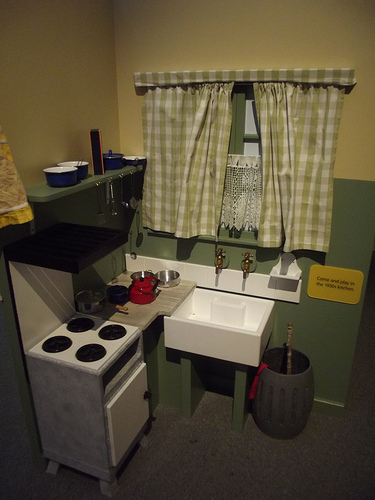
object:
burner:
[40, 335, 72, 355]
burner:
[63, 314, 95, 332]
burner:
[98, 321, 127, 339]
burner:
[74, 342, 106, 366]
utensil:
[108, 177, 122, 218]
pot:
[125, 276, 159, 307]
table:
[78, 268, 196, 428]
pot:
[103, 146, 126, 170]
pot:
[42, 163, 79, 190]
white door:
[107, 362, 153, 466]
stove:
[23, 313, 154, 498]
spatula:
[89, 173, 108, 231]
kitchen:
[0, 0, 375, 498]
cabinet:
[106, 358, 155, 468]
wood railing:
[304, 263, 362, 304]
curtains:
[250, 81, 344, 257]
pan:
[72, 286, 130, 319]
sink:
[160, 290, 275, 368]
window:
[241, 96, 266, 136]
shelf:
[26, 160, 148, 205]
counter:
[99, 268, 198, 332]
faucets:
[240, 250, 254, 278]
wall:
[114, 0, 375, 409]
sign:
[305, 262, 364, 304]